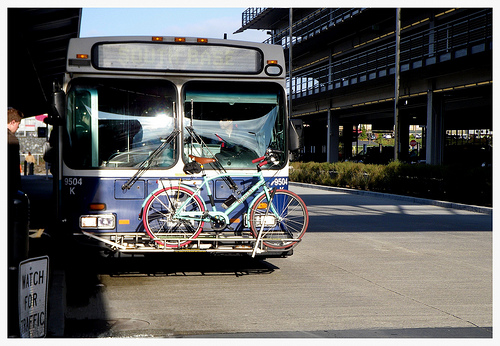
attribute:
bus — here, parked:
[52, 33, 305, 259]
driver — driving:
[215, 114, 239, 151]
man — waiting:
[7, 104, 22, 203]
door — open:
[51, 82, 62, 236]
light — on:
[81, 215, 99, 229]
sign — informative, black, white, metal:
[16, 253, 50, 338]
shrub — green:
[290, 158, 445, 200]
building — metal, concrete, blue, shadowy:
[237, 7, 491, 181]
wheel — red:
[141, 185, 206, 250]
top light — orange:
[150, 34, 165, 42]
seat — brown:
[189, 153, 217, 165]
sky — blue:
[78, 7, 269, 42]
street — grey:
[68, 180, 494, 337]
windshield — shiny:
[65, 79, 287, 171]